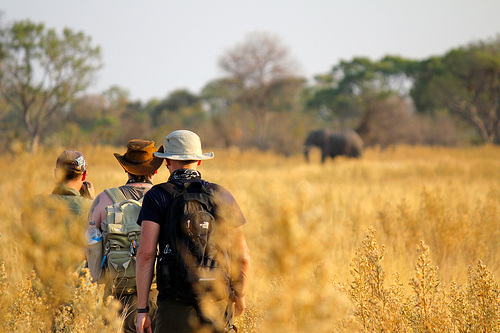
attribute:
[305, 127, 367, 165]
elephant — gray, large, standing, grey, blurry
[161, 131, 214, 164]
hat — tan, brown, beige, white, cream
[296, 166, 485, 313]
grass — yellow, plain, gold, tall, dried, long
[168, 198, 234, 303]
backpack — green, black, large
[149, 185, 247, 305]
shirt — black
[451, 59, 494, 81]
leaves — green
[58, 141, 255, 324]
men — watching, standing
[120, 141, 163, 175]
cap — brown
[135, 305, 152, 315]
watch — black